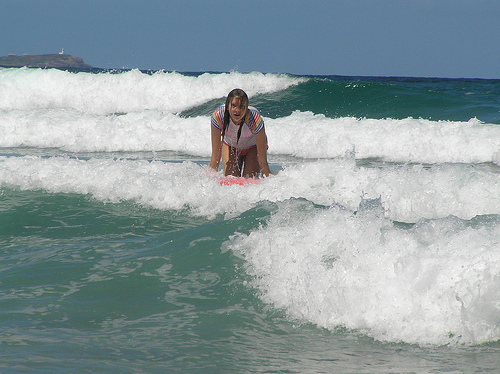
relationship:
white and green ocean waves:
[50, 226, 498, 304] [0, 107, 495, 360]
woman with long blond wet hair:
[201, 87, 280, 184] [226, 99, 263, 153]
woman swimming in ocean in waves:
[201, 87, 280, 184] [298, 172, 414, 327]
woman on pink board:
[201, 87, 280, 184] [207, 163, 283, 188]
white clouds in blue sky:
[305, 8, 360, 66] [6, 6, 497, 65]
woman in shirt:
[201, 87, 280, 184] [208, 105, 270, 152]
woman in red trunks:
[201, 87, 280, 184] [225, 141, 263, 155]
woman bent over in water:
[201, 87, 280, 184] [6, 68, 489, 338]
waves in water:
[0, 68, 498, 340] [6, 69, 497, 370]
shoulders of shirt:
[201, 107, 275, 133] [198, 95, 271, 160]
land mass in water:
[0, 43, 109, 82] [6, 68, 489, 338]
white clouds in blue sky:
[25, 10, 79, 43] [6, 6, 497, 65]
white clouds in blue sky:
[57, 16, 103, 73] [6, 6, 497, 65]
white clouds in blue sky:
[164, 19, 195, 49] [6, 0, 497, 61]